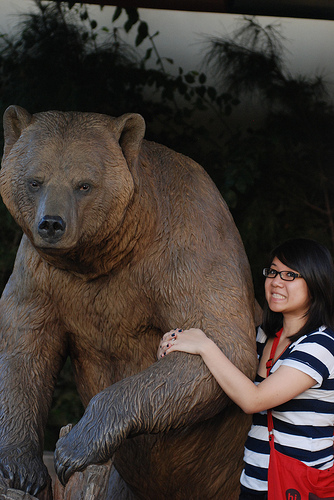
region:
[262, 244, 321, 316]
the head of the girl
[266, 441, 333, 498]
a red bag on the girl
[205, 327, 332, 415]
the arm of the girl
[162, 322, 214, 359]
the hand of the girl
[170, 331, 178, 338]
a black finger nail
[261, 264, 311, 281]
a pair of black glasses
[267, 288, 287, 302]
the mouth of the girl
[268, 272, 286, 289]
the nose of the girl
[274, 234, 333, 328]
the black hair of the girl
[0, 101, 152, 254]
the head on a bear statue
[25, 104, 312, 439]
girl holding arm of large weird plastic bear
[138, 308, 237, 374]
girl has dark blue nail polish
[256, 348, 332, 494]
girl has red purse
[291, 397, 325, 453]
girl's shirt is striped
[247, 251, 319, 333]
girl is making pretend scary face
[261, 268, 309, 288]
girl wearing glasses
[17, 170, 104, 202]
bear has one eye with red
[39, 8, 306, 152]
dark bushes in the background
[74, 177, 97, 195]
bear has one red eye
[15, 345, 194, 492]
large plastic bear holding on to plastic log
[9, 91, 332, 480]
Girl posing with display of a bear.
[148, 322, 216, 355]
Dark finger nail polish.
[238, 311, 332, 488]
A blue and white stripe shirt.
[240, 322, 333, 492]
A short sleeve shirt.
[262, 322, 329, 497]
A red pocket book.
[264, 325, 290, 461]
Long red strap on pocket book.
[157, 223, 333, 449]
A girl with black hair.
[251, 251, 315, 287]
A pair of black glasses.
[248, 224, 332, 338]
Girl is smiling big for camera.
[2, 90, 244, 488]
A bear on display.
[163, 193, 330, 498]
an Asian woman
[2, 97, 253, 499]
a brown statue of a bear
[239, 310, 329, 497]
a red bag over the shoulder of the woman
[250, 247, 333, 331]
glasses on the face of the woman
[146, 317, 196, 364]
blue fingernail polish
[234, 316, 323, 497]
a striped shirt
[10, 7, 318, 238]
a scene in the background of a forest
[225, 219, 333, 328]
has a concerned look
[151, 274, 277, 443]
holding onto the statute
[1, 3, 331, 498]
a scene of a person posing for the camera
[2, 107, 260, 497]
the bear is large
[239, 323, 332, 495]
the girl has a striped shirt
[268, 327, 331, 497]
the girl has a red back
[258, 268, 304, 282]
the girl is wearing glasses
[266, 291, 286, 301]
the girl is smiling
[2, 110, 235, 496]
the bear is brown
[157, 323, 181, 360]
the girl has nail polish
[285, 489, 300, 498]
the purse says hi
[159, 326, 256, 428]
the girl holds the bear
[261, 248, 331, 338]
the girl has dark hair